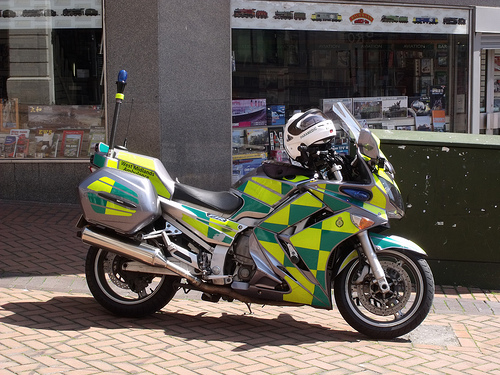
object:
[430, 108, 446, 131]
box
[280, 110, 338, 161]
helmet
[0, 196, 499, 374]
ground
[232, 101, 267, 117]
magazine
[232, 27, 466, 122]
window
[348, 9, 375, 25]
sign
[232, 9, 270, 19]
train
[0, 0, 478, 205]
building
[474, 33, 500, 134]
door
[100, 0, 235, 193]
pillar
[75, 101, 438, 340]
motorbike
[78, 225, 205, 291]
exhaust pipe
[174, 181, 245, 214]
seat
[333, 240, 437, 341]
wheel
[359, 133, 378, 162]
mirror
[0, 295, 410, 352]
shadow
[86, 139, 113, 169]
light